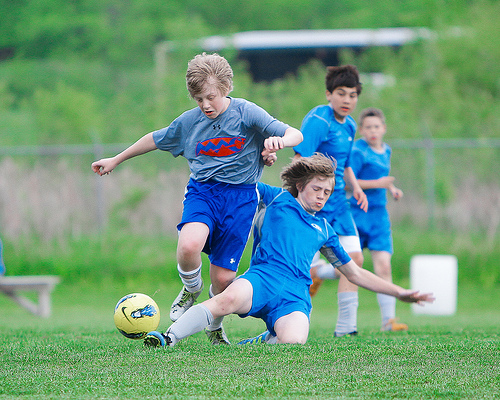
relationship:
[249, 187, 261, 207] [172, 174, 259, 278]
stripe on shorts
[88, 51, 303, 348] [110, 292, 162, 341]
boy are playing soccer ball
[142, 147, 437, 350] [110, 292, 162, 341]
boy are playing soccer ball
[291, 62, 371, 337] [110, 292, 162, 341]
kid are playing soccer ball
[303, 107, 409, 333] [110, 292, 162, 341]
kid are playing soccer ball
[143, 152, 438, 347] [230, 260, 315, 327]
boy has shorts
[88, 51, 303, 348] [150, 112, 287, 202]
boy has shirt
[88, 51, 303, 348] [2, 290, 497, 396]
boy running in grass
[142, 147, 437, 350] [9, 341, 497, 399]
boy falling in grass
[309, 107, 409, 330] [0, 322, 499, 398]
kid standing in grass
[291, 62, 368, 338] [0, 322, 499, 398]
kid standing in grass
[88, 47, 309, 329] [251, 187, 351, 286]
boy in shirt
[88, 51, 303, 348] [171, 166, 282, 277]
boy in pants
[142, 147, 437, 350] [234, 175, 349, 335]
boy in uniform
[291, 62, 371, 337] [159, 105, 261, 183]
kid in uniform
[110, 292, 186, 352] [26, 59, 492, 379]
soccer ball above field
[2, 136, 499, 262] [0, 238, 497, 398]
fence behind field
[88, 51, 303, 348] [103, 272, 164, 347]
boy running at soccer ball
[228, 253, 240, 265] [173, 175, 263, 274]
logo on pants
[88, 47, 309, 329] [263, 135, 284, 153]
boy has hand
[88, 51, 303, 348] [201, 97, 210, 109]
boy has nose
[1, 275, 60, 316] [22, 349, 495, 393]
bench on field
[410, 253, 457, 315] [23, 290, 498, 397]
object on field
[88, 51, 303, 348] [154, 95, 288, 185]
boy wearing shirt